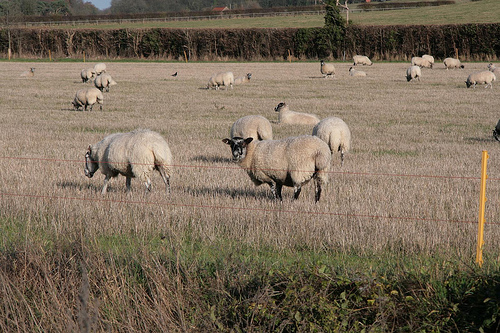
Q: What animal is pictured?
A: Sheep.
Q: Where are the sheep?
A: In a field.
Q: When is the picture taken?
A: Daytime.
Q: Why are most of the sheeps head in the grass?
A: The sheep eat grass.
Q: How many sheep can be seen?
A: 20.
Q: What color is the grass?
A: Tan.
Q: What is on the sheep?
A: Wool.